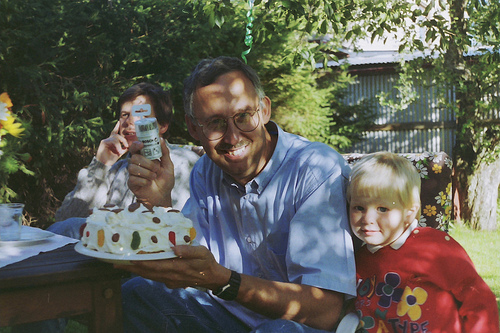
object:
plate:
[74, 241, 178, 260]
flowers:
[355, 309, 375, 333]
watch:
[213, 270, 241, 301]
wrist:
[215, 263, 239, 302]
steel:
[315, 50, 500, 155]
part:
[409, 261, 438, 286]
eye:
[378, 206, 390, 213]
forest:
[0, 0, 400, 222]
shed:
[313, 50, 500, 153]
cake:
[80, 203, 197, 257]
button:
[247, 238, 252, 243]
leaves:
[55, 33, 142, 79]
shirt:
[181, 121, 357, 329]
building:
[315, 51, 500, 154]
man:
[112, 65, 342, 333]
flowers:
[356, 272, 427, 321]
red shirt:
[350, 226, 499, 333]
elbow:
[303, 281, 343, 331]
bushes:
[12, 20, 112, 137]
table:
[0, 241, 130, 333]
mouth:
[360, 229, 381, 236]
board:
[362, 121, 454, 131]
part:
[130, 255, 145, 264]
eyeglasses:
[193, 108, 261, 141]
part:
[306, 227, 338, 268]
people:
[46, 83, 201, 238]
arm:
[216, 175, 345, 330]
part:
[274, 282, 309, 297]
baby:
[349, 152, 499, 333]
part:
[84, 248, 105, 262]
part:
[386, 106, 395, 120]